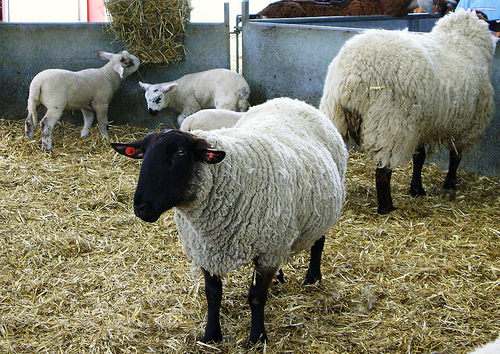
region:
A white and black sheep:
[105, 91, 365, 351]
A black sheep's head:
[107, 124, 232, 226]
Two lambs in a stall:
[24, 49, 256, 150]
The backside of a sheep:
[322, 27, 407, 219]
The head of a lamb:
[133, 76, 180, 118]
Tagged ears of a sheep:
[103, 126, 233, 171]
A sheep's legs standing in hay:
[180, 239, 331, 352]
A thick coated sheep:
[311, 4, 498, 215]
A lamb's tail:
[20, 71, 45, 133]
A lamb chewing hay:
[24, 45, 149, 157]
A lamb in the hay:
[117, 112, 370, 345]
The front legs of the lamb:
[183, 260, 283, 345]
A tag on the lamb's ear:
[113, 137, 141, 155]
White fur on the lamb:
[238, 161, 323, 220]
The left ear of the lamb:
[201, 140, 223, 164]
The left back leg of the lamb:
[308, 240, 335, 295]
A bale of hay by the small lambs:
[126, 15, 176, 55]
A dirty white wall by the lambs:
[265, 36, 323, 86]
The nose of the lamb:
[130, 197, 154, 217]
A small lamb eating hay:
[20, 49, 137, 141]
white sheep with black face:
[121, 113, 198, 228]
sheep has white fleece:
[207, 143, 341, 258]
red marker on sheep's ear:
[111, 138, 170, 178]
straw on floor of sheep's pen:
[376, 221, 452, 317]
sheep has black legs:
[210, 253, 274, 342]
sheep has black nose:
[134, 183, 167, 247]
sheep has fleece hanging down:
[361, 93, 404, 178]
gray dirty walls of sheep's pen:
[278, 23, 328, 90]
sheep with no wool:
[41, 94, 119, 132]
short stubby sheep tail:
[16, 78, 76, 118]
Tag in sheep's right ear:
[120, 143, 136, 158]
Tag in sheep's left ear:
[202, 145, 216, 162]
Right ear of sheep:
[107, 135, 156, 160]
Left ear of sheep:
[191, 140, 229, 168]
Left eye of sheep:
[173, 143, 188, 162]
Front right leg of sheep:
[192, 247, 227, 347]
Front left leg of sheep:
[241, 245, 281, 349]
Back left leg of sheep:
[300, 232, 329, 293]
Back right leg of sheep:
[266, 266, 289, 287]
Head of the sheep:
[117, 127, 210, 230]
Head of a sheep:
[101, 43, 143, 83]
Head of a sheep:
[136, 73, 177, 113]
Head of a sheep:
[98, 130, 233, 229]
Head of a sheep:
[431, 3, 498, 53]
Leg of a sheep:
[38, 103, 60, 160]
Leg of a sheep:
[243, 250, 278, 350]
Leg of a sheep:
[191, 255, 225, 352]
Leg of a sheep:
[305, 225, 330, 299]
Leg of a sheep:
[366, 120, 399, 231]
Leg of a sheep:
[405, 125, 427, 210]